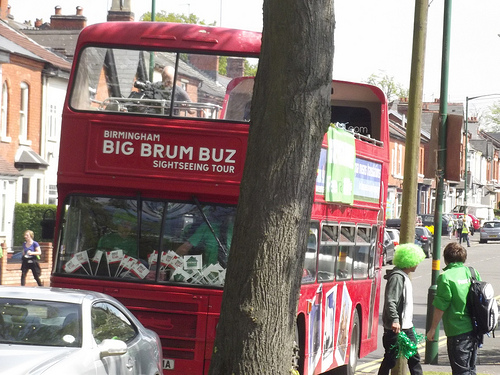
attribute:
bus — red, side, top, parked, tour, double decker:
[69, 97, 334, 363]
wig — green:
[406, 251, 416, 264]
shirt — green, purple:
[449, 298, 465, 320]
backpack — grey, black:
[472, 280, 488, 329]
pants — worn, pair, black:
[444, 331, 479, 366]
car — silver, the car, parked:
[4, 283, 161, 369]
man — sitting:
[149, 68, 183, 102]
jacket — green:
[456, 288, 466, 329]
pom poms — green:
[386, 327, 416, 355]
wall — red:
[8, 74, 27, 86]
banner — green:
[326, 127, 357, 201]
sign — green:
[326, 133, 354, 150]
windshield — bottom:
[121, 210, 202, 237]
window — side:
[193, 60, 246, 121]